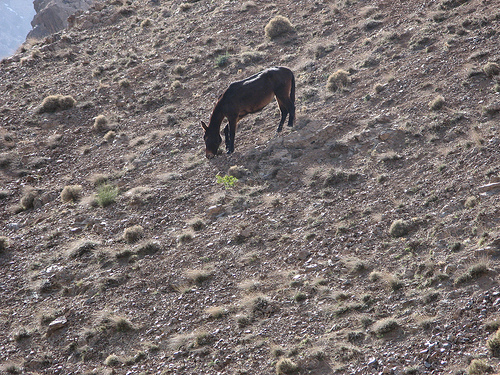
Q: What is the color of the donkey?
A: Black.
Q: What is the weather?
A: Sunny.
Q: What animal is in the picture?
A: Donkey.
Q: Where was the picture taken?
A: On a hilly landscape.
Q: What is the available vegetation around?
A: Dry grass.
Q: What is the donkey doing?
A: Eating dry bush.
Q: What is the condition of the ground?
A: Dry.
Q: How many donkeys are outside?
A: One.